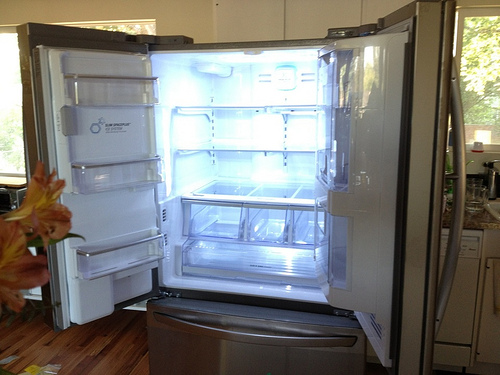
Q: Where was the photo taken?
A: Kitchen.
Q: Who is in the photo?
A: Nobody.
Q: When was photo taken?
A: Daytime.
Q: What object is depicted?
A: Refrigerator.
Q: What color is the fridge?
A: Silver.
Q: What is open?
A: Refrigerator.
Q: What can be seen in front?
A: Flowers.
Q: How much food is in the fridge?
A: None.